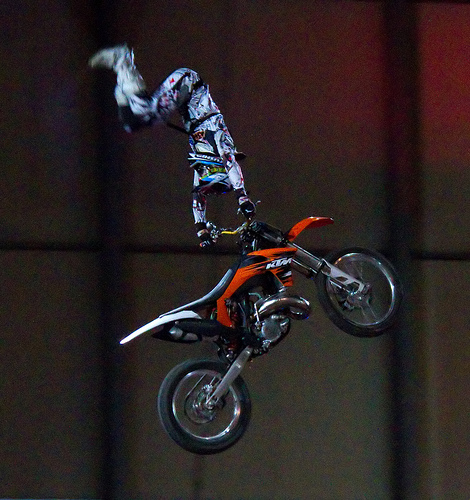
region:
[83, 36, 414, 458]
competitive rider on motorbike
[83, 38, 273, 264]
professional rider upside down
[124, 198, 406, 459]
orange motorbike in the air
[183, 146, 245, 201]
helmet on motorbike rider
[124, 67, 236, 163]
uniform of professional rider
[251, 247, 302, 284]
logo on orange motorbike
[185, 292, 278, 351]
exhaust pipe on motorbike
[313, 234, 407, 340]
front wheel on motorbike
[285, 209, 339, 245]
orange fender on motorbike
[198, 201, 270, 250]
handlebars on front of motorbike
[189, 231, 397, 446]
the motorbike is in the air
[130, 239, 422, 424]
the motorbike is orange and black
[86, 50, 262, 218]
the guy is facing downwards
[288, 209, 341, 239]
the bumper is red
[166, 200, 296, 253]
his hands are holding the handle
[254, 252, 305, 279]
there is writing on the bike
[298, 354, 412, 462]
the background is grey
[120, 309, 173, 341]
the tail of the bike is white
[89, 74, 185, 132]
his knees are bending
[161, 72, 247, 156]
his clothing is white and black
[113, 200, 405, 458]
orange and white bike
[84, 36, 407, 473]
cyclist holding bike in air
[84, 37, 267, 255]
cyclist in blue cycle suit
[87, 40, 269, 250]
cyclist wearing gloves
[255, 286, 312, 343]
chrome exhaust pipe on bike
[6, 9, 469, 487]
motorcycle stunt event scene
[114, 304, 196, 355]
white tail on motorcycle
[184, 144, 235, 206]
blue motorcycle helmet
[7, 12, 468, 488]
dark grey walls in background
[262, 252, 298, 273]
white lettering on orange bike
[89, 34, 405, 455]
biker upside down in air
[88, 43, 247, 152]
knees bent over motorcycle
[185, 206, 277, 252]
biker holding onto handlebars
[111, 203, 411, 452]
red motorcycle with white highlights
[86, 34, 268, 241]
biker wearing colorful outfit with different images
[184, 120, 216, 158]
image of helmeted person on front of outfit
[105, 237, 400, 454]
one wheel higher than the other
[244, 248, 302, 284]
white letters on side of motorcycle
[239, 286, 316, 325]
curved pipe on bottom of bike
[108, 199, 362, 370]
points on front and back of motorcycle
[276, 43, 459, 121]
light red back ground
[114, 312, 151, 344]
white tip of bike handle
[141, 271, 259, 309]
solid black seat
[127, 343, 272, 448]
large black wheel on bike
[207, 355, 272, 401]
silver spokes on the bike wheel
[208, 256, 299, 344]
red trim on bike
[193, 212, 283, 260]
black and silver glove on man's hand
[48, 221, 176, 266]
large black line on wall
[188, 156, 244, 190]
black and blue helmet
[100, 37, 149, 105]
white boots on biker